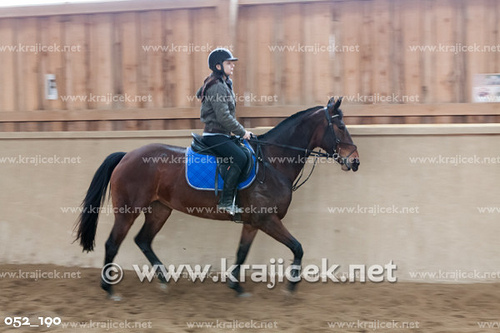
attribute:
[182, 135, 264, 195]
pad — blue 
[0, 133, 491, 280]
wall — cement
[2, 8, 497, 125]
wall — brown 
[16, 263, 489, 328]
dirt — brown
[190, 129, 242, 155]
saddle — leather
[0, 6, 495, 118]
fence — wood 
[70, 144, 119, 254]
tail — flowing, black